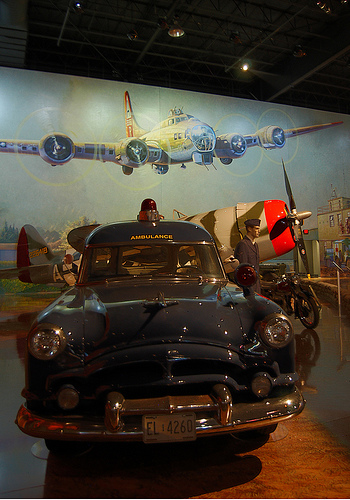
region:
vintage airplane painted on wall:
[6, 85, 348, 184]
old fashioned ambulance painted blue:
[12, 188, 313, 450]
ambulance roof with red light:
[87, 193, 223, 245]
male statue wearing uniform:
[213, 198, 323, 336]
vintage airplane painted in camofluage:
[15, 155, 337, 255]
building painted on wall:
[278, 180, 345, 284]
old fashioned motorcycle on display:
[243, 250, 338, 338]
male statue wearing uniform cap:
[225, 204, 278, 291]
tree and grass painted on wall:
[3, 211, 164, 330]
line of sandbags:
[297, 268, 349, 305]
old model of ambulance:
[28, 194, 302, 451]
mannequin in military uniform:
[235, 215, 265, 299]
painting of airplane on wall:
[3, 72, 346, 181]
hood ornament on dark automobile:
[138, 287, 183, 317]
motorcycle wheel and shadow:
[291, 287, 326, 368]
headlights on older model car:
[22, 311, 292, 359]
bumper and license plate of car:
[12, 379, 309, 447]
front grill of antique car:
[15, 346, 296, 405]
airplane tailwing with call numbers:
[5, 217, 67, 290]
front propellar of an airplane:
[263, 157, 321, 280]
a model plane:
[6, 106, 348, 198]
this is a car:
[6, 197, 319, 460]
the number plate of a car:
[141, 408, 209, 442]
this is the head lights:
[259, 316, 301, 351]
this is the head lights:
[25, 304, 75, 371]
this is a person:
[223, 200, 289, 313]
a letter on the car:
[123, 225, 196, 251]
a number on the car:
[161, 414, 179, 439]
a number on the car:
[171, 417, 181, 441]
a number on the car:
[187, 418, 196, 436]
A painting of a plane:
[1, 90, 342, 175]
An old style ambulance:
[16, 198, 300, 447]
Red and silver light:
[137, 198, 161, 222]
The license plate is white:
[142, 413, 194, 443]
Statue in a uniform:
[235, 218, 261, 294]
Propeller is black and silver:
[280, 159, 313, 280]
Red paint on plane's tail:
[15, 228, 27, 283]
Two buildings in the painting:
[295, 183, 348, 272]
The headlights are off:
[30, 315, 292, 357]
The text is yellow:
[131, 234, 173, 240]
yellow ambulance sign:
[128, 232, 176, 240]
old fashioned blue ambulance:
[30, 198, 305, 437]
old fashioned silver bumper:
[12, 388, 313, 439]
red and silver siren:
[135, 196, 164, 223]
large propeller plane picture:
[3, 88, 349, 198]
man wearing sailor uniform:
[237, 216, 264, 268]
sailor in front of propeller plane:
[223, 159, 321, 274]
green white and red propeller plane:
[211, 186, 309, 266]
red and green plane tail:
[6, 224, 75, 293]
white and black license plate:
[139, 412, 200, 444]